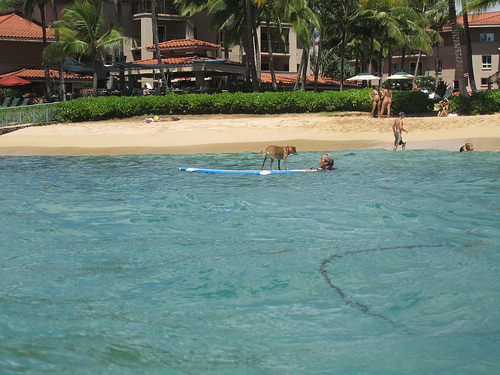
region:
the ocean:
[10, 163, 490, 359]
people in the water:
[319, 110, 485, 187]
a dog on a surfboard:
[176, 136, 318, 191]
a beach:
[16, 103, 497, 168]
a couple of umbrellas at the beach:
[342, 62, 422, 92]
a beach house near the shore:
[76, 26, 313, 113]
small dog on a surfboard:
[178, 145, 318, 177]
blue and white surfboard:
[175, 163, 317, 178]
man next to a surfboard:
[179, 150, 338, 175]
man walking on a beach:
[388, 105, 410, 152]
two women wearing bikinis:
[367, 80, 394, 120]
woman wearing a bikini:
[437, 95, 457, 119]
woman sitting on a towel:
[435, 94, 458, 117]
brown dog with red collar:
[257, 143, 299, 175]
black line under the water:
[318, 240, 451, 338]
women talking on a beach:
[367, 81, 395, 119]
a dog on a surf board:
[258, 133, 301, 170]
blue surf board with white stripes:
[175, 161, 319, 177]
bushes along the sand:
[62, 83, 425, 119]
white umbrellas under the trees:
[346, 70, 420, 86]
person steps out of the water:
[388, 106, 415, 154]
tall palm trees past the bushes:
[171, 2, 475, 82]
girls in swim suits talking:
[368, 80, 395, 117]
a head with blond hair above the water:
[313, 148, 341, 175]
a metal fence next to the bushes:
[0, 101, 50, 131]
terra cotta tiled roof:
[149, 36, 221, 52]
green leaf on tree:
[363, 10, 406, 43]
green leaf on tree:
[399, 15, 431, 40]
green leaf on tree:
[426, 27, 446, 44]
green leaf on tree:
[97, 28, 124, 50]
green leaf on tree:
[61, 40, 92, 57]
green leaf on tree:
[64, 4, 91, 41]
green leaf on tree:
[456, 0, 498, 17]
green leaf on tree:
[272, 10, 284, 37]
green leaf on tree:
[213, 8, 243, 35]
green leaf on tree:
[178, 1, 198, 16]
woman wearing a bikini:
[380, 74, 397, 123]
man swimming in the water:
[312, 149, 338, 179]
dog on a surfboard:
[248, 133, 300, 171]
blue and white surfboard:
[183, 158, 318, 180]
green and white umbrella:
[345, 63, 375, 87]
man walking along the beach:
[393, 108, 413, 150]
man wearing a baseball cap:
[388, 106, 416, 151]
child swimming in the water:
[466, 138, 478, 155]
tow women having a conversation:
[358, 80, 398, 126]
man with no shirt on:
[386, 109, 417, 160]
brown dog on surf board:
[260, 140, 299, 170]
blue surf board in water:
[193, 163, 302, 180]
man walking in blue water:
[388, 105, 414, 165]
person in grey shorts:
[391, 108, 408, 148]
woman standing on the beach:
[378, 83, 393, 115]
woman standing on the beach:
[369, 82, 381, 117]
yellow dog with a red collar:
[258, 143, 297, 169]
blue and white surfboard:
[179, 164, 316, 176]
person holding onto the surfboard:
[305, 151, 335, 172]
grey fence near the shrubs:
[2, 103, 51, 127]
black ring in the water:
[320, 242, 491, 337]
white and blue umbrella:
[346, 70, 376, 81]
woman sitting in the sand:
[436, 96, 450, 116]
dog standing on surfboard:
[260, 145, 299, 173]